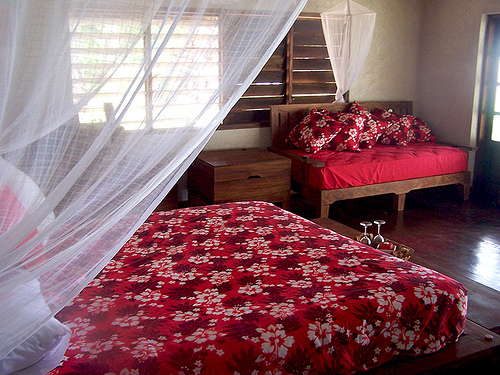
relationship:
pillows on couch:
[296, 103, 432, 146] [301, 153, 470, 187]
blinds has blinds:
[68, 7, 341, 129] [269, 37, 321, 97]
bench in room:
[474, 284, 496, 319] [4, 5, 495, 374]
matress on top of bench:
[198, 208, 348, 357] [474, 284, 496, 319]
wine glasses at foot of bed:
[356, 214, 387, 250] [198, 210, 474, 363]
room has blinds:
[4, 5, 495, 374] [68, 7, 341, 129]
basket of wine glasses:
[398, 247, 412, 259] [356, 214, 387, 250]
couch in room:
[268, 98, 478, 219] [4, 5, 495, 374]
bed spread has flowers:
[40, 200, 466, 375] [227, 210, 261, 222]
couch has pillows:
[268, 98, 478, 219] [296, 103, 432, 146]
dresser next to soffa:
[247, 157, 289, 184] [328, 156, 359, 196]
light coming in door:
[488, 43, 497, 110] [469, 4, 500, 177]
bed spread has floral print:
[231, 215, 295, 279] [337, 251, 370, 275]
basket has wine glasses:
[398, 247, 412, 259] [356, 214, 387, 250]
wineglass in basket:
[353, 212, 373, 254] [398, 247, 412, 259]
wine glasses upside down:
[356, 214, 387, 250] [359, 236, 373, 245]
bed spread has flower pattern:
[40, 200, 466, 375] [306, 119, 328, 135]